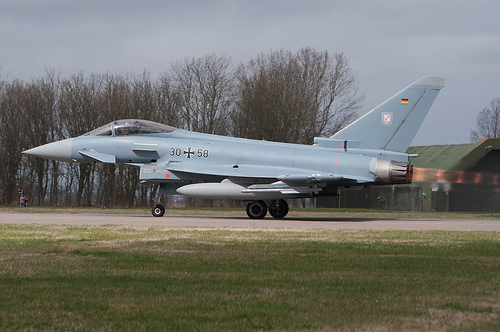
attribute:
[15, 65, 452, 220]
jet — gray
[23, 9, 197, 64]
clouds — white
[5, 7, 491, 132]
sky — blue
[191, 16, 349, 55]
clouds — white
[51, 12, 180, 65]
sky — blue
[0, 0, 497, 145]
clouds — white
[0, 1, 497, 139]
sky — blue, grey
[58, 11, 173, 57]
sky — blue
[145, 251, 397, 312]
grass — low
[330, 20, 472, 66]
clouds — white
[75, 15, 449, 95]
sky — blue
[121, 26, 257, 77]
clouds — white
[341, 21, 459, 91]
sky — blue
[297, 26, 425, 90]
clouds — white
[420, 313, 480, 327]
spot — bare